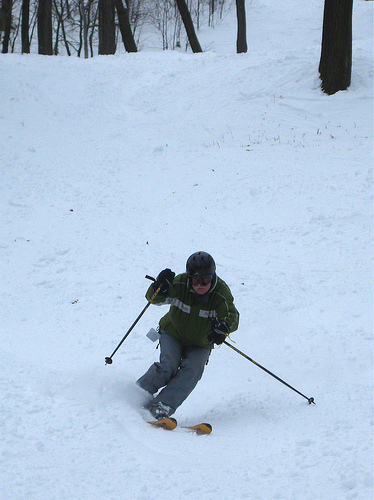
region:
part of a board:
[195, 427, 205, 452]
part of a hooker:
[272, 360, 315, 389]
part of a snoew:
[265, 396, 297, 433]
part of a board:
[154, 407, 171, 448]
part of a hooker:
[286, 375, 325, 400]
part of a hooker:
[293, 375, 337, 411]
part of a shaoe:
[154, 388, 175, 435]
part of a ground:
[296, 357, 327, 379]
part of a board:
[196, 410, 221, 455]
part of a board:
[192, 393, 228, 464]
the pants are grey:
[149, 343, 203, 409]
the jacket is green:
[166, 273, 230, 336]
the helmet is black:
[187, 249, 221, 282]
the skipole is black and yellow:
[219, 340, 308, 407]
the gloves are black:
[152, 266, 170, 286]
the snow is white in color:
[99, 463, 178, 495]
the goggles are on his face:
[191, 275, 216, 288]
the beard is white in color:
[191, 281, 209, 295]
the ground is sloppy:
[0, 70, 349, 498]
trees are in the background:
[62, 8, 214, 45]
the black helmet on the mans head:
[183, 245, 218, 277]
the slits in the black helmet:
[190, 250, 211, 265]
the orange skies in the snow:
[142, 416, 213, 440]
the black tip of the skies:
[167, 413, 215, 430]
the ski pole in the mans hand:
[206, 325, 317, 407]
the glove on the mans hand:
[207, 317, 227, 347]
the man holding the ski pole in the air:
[98, 267, 177, 376]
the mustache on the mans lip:
[191, 282, 209, 293]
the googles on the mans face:
[184, 271, 216, 288]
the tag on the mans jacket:
[144, 321, 163, 343]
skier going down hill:
[77, 245, 349, 453]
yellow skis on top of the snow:
[140, 414, 223, 438]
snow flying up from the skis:
[102, 367, 141, 405]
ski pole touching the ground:
[264, 373, 332, 432]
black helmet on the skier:
[177, 247, 217, 294]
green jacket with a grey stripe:
[167, 275, 245, 343]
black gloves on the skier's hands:
[144, 269, 178, 301]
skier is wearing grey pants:
[132, 333, 212, 404]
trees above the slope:
[20, 8, 255, 55]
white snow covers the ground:
[23, 402, 114, 465]